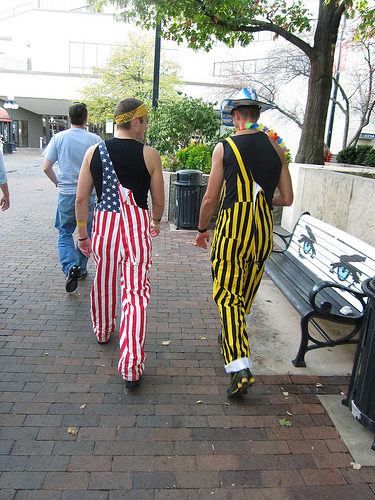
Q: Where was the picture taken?
A: It was taken at the sidewalk.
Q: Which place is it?
A: It is a sidewalk.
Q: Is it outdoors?
A: Yes, it is outdoors.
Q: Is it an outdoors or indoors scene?
A: It is outdoors.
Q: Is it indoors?
A: No, it is outdoors.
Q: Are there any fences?
A: No, there are no fences.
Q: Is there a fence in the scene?
A: No, there are no fences.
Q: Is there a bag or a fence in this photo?
A: No, there are no fences or bags.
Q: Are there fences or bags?
A: No, there are no fences or bags.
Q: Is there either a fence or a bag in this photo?
A: No, there are no fences or bags.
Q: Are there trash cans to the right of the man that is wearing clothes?
A: No, the trash can is to the left of the man.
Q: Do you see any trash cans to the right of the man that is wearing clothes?
A: No, the trash can is to the left of the man.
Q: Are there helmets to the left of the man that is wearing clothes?
A: No, there is a trash can to the left of the man.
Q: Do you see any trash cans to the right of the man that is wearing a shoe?
A: Yes, there is a trash can to the right of the man.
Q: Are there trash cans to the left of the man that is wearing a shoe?
A: No, the trash can is to the right of the man.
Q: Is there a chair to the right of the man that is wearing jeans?
A: No, there is a trash can to the right of the man.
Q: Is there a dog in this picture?
A: No, there are no dogs.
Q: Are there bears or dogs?
A: No, there are no dogs or bears.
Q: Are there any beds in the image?
A: No, there are no beds.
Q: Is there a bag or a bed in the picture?
A: No, there are no beds or bags.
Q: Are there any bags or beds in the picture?
A: No, there are no beds or bags.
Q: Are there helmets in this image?
A: No, there are no helmets.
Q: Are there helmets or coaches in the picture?
A: No, there are no helmets or coaches.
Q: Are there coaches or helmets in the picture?
A: No, there are no helmets or coaches.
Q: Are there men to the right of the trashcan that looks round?
A: Yes, there is a man to the right of the garbage can.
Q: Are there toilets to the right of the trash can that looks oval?
A: No, there is a man to the right of the garbage can.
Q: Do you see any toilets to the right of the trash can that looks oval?
A: No, there is a man to the right of the garbage can.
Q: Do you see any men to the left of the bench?
A: Yes, there is a man to the left of the bench.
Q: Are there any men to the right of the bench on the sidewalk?
A: No, the man is to the left of the bench.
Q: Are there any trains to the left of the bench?
A: No, there is a man to the left of the bench.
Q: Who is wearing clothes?
A: The man is wearing clothes.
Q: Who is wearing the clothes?
A: The man is wearing clothes.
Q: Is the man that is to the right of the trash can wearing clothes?
A: Yes, the man is wearing clothes.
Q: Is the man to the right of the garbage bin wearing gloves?
A: No, the man is wearing clothes.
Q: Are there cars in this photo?
A: No, there are no cars.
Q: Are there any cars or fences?
A: No, there are no cars or fences.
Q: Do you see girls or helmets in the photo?
A: No, there are no girls or helmets.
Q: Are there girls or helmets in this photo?
A: No, there are no girls or helmets.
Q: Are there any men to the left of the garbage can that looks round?
A: Yes, there is a man to the left of the garbage bin.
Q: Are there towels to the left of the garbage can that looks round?
A: No, there is a man to the left of the trash can.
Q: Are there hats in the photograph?
A: Yes, there is a hat.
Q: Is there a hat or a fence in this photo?
A: Yes, there is a hat.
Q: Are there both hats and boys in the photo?
A: No, there is a hat but no boys.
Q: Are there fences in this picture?
A: No, there are no fences.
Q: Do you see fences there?
A: No, there are no fences.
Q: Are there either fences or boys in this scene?
A: No, there are no fences or boys.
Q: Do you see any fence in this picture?
A: No, there are no fences.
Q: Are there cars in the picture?
A: No, there are no cars.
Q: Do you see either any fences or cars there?
A: No, there are no cars or fences.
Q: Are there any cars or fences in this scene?
A: No, there are no cars or fences.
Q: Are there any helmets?
A: No, there are no helmets.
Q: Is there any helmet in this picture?
A: No, there are no helmets.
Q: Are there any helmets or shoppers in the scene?
A: No, there are no helmets or shoppers.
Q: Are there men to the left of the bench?
A: Yes, there are men to the left of the bench.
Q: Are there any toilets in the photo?
A: No, there are no toilets.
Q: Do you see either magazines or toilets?
A: No, there are no toilets or magazines.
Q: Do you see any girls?
A: No, there are no girls.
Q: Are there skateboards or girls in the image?
A: No, there are no girls or skateboards.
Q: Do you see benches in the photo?
A: Yes, there is a bench.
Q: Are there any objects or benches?
A: Yes, there is a bench.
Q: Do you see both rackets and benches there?
A: No, there is a bench but no rackets.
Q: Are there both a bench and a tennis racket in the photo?
A: No, there is a bench but no rackets.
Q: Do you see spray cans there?
A: No, there are no spray cans.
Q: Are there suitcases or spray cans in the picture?
A: No, there are no spray cans or suitcases.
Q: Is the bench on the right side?
A: Yes, the bench is on the right of the image.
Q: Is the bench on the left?
A: No, the bench is on the right of the image.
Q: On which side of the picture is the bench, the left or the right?
A: The bench is on the right of the image.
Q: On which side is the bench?
A: The bench is on the right of the image.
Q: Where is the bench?
A: The bench is on the sidewalk.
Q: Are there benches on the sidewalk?
A: Yes, there is a bench on the sidewalk.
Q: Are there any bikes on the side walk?
A: No, there is a bench on the side walk.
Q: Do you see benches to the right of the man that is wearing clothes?
A: Yes, there is a bench to the right of the man.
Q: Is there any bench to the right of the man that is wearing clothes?
A: Yes, there is a bench to the right of the man.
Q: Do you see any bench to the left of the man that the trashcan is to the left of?
A: No, the bench is to the right of the man.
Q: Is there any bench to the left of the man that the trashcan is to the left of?
A: No, the bench is to the right of the man.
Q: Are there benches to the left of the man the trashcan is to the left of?
A: No, the bench is to the right of the man.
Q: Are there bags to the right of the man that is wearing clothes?
A: No, there is a bench to the right of the man.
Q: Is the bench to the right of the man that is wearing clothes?
A: Yes, the bench is to the right of the man.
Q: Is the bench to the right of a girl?
A: No, the bench is to the right of the man.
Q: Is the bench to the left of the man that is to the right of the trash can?
A: No, the bench is to the right of the man.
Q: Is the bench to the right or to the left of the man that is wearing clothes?
A: The bench is to the right of the man.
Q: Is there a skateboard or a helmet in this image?
A: No, there are no helmets or skateboards.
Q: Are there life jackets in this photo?
A: No, there are no life jackets.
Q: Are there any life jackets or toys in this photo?
A: No, there are no life jackets or toys.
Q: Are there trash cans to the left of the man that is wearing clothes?
A: Yes, there is a trash can to the left of the man.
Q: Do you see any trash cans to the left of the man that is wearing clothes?
A: Yes, there is a trash can to the left of the man.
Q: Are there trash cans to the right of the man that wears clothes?
A: No, the trash can is to the left of the man.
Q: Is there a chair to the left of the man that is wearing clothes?
A: No, there is a trash can to the left of the man.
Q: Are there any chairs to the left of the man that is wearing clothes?
A: No, there is a trash can to the left of the man.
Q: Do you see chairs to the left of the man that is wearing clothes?
A: No, there is a trash can to the left of the man.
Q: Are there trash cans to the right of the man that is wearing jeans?
A: Yes, there is a trash can to the right of the man.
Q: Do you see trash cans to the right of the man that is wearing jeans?
A: Yes, there is a trash can to the right of the man.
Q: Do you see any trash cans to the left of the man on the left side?
A: No, the trash can is to the right of the man.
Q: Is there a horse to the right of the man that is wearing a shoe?
A: No, there is a trash can to the right of the man.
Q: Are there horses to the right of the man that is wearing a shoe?
A: No, there is a trash can to the right of the man.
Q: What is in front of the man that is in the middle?
A: The trash bin is in front of the man.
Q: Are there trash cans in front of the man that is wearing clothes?
A: Yes, there is a trash can in front of the man.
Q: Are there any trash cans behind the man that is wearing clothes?
A: No, the trash can is in front of the man.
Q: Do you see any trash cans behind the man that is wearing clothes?
A: No, the trash can is in front of the man.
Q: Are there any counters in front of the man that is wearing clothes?
A: No, there is a trash can in front of the man.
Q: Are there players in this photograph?
A: No, there are no players.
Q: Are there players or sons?
A: No, there are no players or sons.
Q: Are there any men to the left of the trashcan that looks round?
A: Yes, there is a man to the left of the trash can.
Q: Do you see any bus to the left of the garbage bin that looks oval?
A: No, there is a man to the left of the trash can.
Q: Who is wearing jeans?
A: The man is wearing jeans.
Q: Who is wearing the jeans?
A: The man is wearing jeans.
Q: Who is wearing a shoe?
A: The man is wearing a shoe.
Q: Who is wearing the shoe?
A: The man is wearing a shoe.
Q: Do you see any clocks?
A: No, there are no clocks.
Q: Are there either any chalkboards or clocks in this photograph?
A: No, there are no clocks or chalkboards.